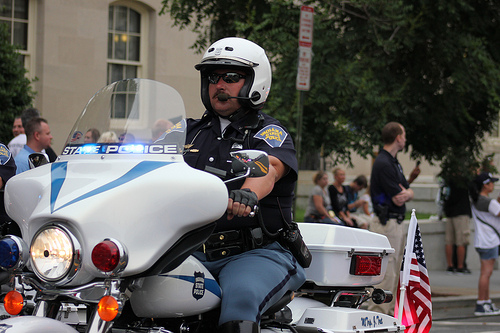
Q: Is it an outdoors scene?
A: Yes, it is outdoors.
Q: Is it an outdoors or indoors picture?
A: It is outdoors.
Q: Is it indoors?
A: No, it is outdoors.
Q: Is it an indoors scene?
A: No, it is outdoors.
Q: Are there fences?
A: No, there are no fences.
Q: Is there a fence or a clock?
A: No, there are no fences or clocks.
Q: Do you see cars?
A: No, there are no cars.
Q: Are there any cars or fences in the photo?
A: No, there are no cars or fences.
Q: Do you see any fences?
A: No, there are no fences.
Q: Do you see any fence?
A: No, there are no fences.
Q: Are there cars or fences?
A: No, there are no fences or cars.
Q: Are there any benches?
A: No, there are no benches.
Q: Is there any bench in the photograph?
A: No, there are no benches.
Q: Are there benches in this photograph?
A: No, there are no benches.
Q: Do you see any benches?
A: No, there are no benches.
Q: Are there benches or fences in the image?
A: No, there are no benches or fences.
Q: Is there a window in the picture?
A: Yes, there is a window.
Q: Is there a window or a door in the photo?
A: Yes, there is a window.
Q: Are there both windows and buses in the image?
A: No, there is a window but no buses.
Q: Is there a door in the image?
A: No, there are no doors.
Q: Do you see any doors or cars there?
A: No, there are no doors or cars.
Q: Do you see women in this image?
A: Yes, there is a woman.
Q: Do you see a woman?
A: Yes, there is a woman.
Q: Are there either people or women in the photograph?
A: Yes, there is a woman.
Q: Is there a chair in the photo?
A: No, there are no chairs.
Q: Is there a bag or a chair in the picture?
A: No, there are no chairs or bags.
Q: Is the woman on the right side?
A: Yes, the woman is on the right of the image.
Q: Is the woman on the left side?
A: No, the woman is on the right of the image.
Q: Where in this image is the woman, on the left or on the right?
A: The woman is on the right of the image.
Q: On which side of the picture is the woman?
A: The woman is on the right of the image.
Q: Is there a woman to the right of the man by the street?
A: Yes, there is a woman to the right of the man.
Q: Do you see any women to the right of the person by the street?
A: Yes, there is a woman to the right of the man.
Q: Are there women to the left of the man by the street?
A: No, the woman is to the right of the man.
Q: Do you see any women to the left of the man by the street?
A: No, the woman is to the right of the man.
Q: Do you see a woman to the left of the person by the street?
A: No, the woman is to the right of the man.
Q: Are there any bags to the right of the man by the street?
A: No, there is a woman to the right of the man.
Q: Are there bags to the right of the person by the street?
A: No, there is a woman to the right of the man.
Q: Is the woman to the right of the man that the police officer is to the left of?
A: Yes, the woman is to the right of the man.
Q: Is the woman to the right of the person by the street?
A: Yes, the woman is to the right of the man.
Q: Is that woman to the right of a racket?
A: No, the woman is to the right of the man.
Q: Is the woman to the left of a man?
A: No, the woman is to the right of a man.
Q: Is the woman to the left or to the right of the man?
A: The woman is to the right of the man.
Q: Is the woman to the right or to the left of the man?
A: The woman is to the right of the man.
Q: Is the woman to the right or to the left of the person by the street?
A: The woman is to the right of the man.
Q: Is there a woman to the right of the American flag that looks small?
A: Yes, there is a woman to the right of the American flag.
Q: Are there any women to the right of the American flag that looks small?
A: Yes, there is a woman to the right of the American flag.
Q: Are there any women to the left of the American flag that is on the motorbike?
A: No, the woman is to the right of the American flag.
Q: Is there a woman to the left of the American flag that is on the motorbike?
A: No, the woman is to the right of the American flag.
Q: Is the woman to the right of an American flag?
A: Yes, the woman is to the right of an American flag.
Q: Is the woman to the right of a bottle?
A: No, the woman is to the right of an American flag.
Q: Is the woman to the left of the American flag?
A: No, the woman is to the right of the American flag.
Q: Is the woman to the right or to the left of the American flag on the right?
A: The woman is to the right of the American flag.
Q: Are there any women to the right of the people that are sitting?
A: Yes, there is a woman to the right of the people.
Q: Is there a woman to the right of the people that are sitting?
A: Yes, there is a woman to the right of the people.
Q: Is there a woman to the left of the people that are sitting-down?
A: No, the woman is to the right of the people.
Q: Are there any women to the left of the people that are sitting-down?
A: No, the woman is to the right of the people.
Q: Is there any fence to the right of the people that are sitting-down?
A: No, there is a woman to the right of the people.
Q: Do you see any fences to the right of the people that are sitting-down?
A: No, there is a woman to the right of the people.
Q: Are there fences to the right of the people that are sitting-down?
A: No, there is a woman to the right of the people.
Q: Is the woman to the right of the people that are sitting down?
A: Yes, the woman is to the right of the people.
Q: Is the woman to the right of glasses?
A: No, the woman is to the right of the people.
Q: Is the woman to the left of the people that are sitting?
A: No, the woman is to the right of the people.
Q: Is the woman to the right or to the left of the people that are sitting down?
A: The woman is to the right of the people.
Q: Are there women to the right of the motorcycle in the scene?
A: Yes, there is a woman to the right of the motorcycle.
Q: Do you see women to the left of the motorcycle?
A: No, the woman is to the right of the motorcycle.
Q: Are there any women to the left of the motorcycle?
A: No, the woman is to the right of the motorcycle.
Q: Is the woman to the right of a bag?
A: No, the woman is to the right of the motorcycle.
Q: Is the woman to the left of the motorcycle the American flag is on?
A: No, the woman is to the right of the motorcycle.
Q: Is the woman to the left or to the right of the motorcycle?
A: The woman is to the right of the motorcycle.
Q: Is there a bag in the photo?
A: No, there are no bags.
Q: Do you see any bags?
A: No, there are no bags.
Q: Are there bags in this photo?
A: No, there are no bags.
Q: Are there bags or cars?
A: No, there are no bags or cars.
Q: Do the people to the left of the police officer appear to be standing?
A: Yes, the people are standing.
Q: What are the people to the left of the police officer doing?
A: The people are standing.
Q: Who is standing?
A: The people are standing.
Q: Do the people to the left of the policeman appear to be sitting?
A: No, the people are standing.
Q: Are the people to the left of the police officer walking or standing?
A: The people are standing.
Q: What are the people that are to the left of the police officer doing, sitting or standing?
A: The people are standing.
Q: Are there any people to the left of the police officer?
A: Yes, there are people to the left of the police officer.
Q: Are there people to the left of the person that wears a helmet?
A: Yes, there are people to the left of the police officer.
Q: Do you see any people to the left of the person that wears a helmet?
A: Yes, there are people to the left of the police officer.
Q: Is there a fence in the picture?
A: No, there are no fences.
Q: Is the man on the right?
A: Yes, the man is on the right of the image.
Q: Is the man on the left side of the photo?
A: No, the man is on the right of the image.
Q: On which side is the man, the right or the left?
A: The man is on the right of the image.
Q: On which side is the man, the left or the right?
A: The man is on the right of the image.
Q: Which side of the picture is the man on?
A: The man is on the right of the image.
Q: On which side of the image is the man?
A: The man is on the right of the image.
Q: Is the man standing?
A: Yes, the man is standing.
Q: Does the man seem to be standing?
A: Yes, the man is standing.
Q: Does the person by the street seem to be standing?
A: Yes, the man is standing.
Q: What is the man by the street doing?
A: The man is standing.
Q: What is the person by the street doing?
A: The man is standing.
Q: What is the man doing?
A: The man is standing.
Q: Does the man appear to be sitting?
A: No, the man is standing.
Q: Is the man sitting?
A: No, the man is standing.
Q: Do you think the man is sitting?
A: No, the man is standing.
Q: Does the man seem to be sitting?
A: No, the man is standing.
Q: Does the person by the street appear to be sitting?
A: No, the man is standing.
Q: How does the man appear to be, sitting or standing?
A: The man is standing.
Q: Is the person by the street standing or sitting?
A: The man is standing.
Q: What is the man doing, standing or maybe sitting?
A: The man is standing.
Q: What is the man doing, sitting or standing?
A: The man is standing.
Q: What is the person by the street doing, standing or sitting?
A: The man is standing.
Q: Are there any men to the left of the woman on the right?
A: Yes, there is a man to the left of the woman.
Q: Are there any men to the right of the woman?
A: No, the man is to the left of the woman.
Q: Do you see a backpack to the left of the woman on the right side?
A: No, there is a man to the left of the woman.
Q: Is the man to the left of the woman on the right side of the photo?
A: Yes, the man is to the left of the woman.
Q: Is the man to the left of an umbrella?
A: No, the man is to the left of the woman.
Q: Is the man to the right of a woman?
A: No, the man is to the left of a woman.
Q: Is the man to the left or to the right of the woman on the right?
A: The man is to the left of the woman.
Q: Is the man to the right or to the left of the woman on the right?
A: The man is to the left of the woman.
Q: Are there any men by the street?
A: Yes, there is a man by the street.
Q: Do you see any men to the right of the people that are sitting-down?
A: Yes, there is a man to the right of the people.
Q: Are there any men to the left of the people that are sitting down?
A: No, the man is to the right of the people.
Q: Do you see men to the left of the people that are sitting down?
A: No, the man is to the right of the people.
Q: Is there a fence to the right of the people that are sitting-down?
A: No, there is a man to the right of the people.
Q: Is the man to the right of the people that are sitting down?
A: Yes, the man is to the right of the people.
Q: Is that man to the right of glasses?
A: No, the man is to the right of the people.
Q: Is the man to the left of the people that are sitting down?
A: No, the man is to the right of the people.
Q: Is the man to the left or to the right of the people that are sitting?
A: The man is to the right of the people.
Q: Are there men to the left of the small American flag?
A: Yes, there is a man to the left of the American flag.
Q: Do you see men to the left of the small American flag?
A: Yes, there is a man to the left of the American flag.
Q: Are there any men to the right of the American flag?
A: No, the man is to the left of the American flag.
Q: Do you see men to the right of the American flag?
A: No, the man is to the left of the American flag.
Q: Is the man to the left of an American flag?
A: Yes, the man is to the left of an American flag.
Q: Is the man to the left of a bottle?
A: No, the man is to the left of an American flag.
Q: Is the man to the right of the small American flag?
A: No, the man is to the left of the American flag.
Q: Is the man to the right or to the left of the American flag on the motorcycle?
A: The man is to the left of the American flag.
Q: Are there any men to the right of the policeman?
A: Yes, there is a man to the right of the policeman.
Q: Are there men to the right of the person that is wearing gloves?
A: Yes, there is a man to the right of the policeman.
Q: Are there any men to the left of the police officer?
A: No, the man is to the right of the police officer.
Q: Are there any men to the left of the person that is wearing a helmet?
A: No, the man is to the right of the police officer.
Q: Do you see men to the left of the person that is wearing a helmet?
A: No, the man is to the right of the police officer.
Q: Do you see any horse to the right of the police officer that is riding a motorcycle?
A: No, there is a man to the right of the police officer.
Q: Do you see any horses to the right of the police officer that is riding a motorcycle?
A: No, there is a man to the right of the police officer.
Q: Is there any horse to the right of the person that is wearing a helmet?
A: No, there is a man to the right of the police officer.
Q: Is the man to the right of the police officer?
A: Yes, the man is to the right of the police officer.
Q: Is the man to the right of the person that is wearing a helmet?
A: Yes, the man is to the right of the police officer.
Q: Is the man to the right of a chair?
A: No, the man is to the right of the police officer.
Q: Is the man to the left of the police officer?
A: No, the man is to the right of the police officer.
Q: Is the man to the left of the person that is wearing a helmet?
A: No, the man is to the right of the police officer.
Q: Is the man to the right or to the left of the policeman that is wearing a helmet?
A: The man is to the right of the policeman.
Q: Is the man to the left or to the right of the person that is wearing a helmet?
A: The man is to the right of the policeman.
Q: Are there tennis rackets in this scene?
A: No, there are no tennis rackets.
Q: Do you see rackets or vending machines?
A: No, there are no rackets or vending machines.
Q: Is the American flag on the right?
A: Yes, the American flag is on the right of the image.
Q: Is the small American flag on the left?
A: No, the American flag is on the right of the image.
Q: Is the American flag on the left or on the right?
A: The American flag is on the right of the image.